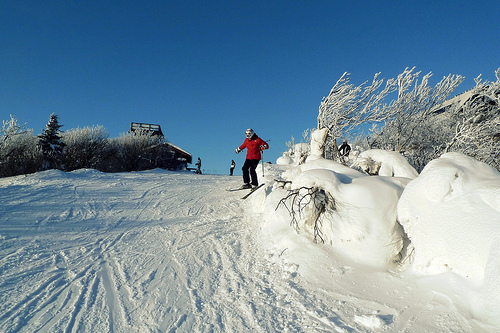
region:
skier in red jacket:
[222, 115, 274, 220]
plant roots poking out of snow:
[274, 172, 360, 250]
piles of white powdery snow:
[394, 141, 499, 278]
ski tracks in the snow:
[36, 181, 188, 308]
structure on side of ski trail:
[123, 112, 193, 176]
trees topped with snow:
[5, 97, 125, 184]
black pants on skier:
[224, 156, 270, 206]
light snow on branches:
[321, 50, 428, 151]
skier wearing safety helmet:
[243, 125, 255, 143]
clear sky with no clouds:
[132, 17, 286, 92]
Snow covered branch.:
[272, 173, 339, 249]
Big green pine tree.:
[35, 105, 65, 155]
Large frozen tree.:
[305, 65, 375, 140]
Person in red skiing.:
[225, 125, 265, 200]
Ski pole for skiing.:
[251, 135, 271, 175]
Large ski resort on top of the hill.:
[120, 116, 195, 171]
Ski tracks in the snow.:
[41, 232, 131, 323]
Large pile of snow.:
[400, 142, 491, 275]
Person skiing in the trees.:
[330, 131, 353, 157]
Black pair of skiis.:
[218, 178, 267, 201]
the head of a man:
[241, 124, 259, 141]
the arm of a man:
[253, 135, 272, 153]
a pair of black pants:
[239, 153, 262, 186]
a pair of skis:
[223, 177, 270, 207]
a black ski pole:
[257, 147, 269, 179]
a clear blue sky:
[0, 0, 499, 180]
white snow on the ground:
[0, 164, 499, 331]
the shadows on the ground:
[0, 175, 215, 297]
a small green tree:
[32, 105, 69, 167]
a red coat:
[236, 131, 271, 162]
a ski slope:
[4, 48, 498, 321]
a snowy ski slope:
[1, 56, 496, 328]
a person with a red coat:
[231, 115, 278, 207]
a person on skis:
[222, 118, 280, 218]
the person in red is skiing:
[228, 119, 278, 208]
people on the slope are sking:
[189, 118, 275, 215]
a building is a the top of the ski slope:
[121, 114, 191, 176]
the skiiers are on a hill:
[135, 113, 394, 260]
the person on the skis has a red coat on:
[229, 122, 276, 205]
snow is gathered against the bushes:
[253, 127, 498, 325]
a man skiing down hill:
[227, 127, 274, 204]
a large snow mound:
[397, 152, 494, 284]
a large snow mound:
[289, 158, 406, 270]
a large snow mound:
[354, 145, 412, 176]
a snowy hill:
[4, 150, 349, 330]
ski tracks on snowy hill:
[19, 165, 188, 330]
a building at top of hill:
[123, 119, 195, 169]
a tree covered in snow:
[311, 66, 386, 147]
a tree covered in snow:
[389, 65, 451, 153]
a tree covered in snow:
[34, 112, 61, 164]